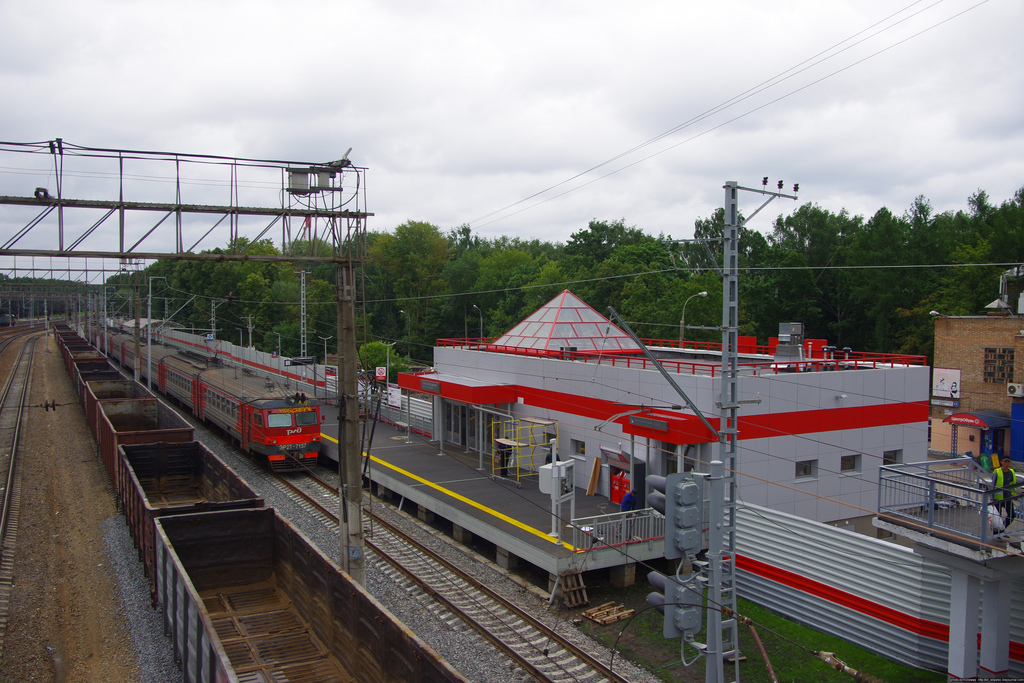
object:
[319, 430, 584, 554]
yellow line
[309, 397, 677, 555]
platform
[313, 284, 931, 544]
train station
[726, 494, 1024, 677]
metal fence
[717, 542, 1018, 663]
red stripe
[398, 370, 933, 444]
red stripe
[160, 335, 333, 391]
red stripe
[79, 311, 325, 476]
train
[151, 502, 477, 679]
empty traincar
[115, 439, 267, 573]
empty traincar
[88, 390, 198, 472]
empty traincar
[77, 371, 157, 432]
empty traincar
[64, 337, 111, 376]
empty traincar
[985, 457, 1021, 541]
person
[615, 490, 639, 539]
person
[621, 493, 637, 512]
blue jacket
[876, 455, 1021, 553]
railing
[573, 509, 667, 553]
railing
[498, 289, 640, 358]
pyramid roof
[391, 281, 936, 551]
building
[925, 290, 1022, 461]
building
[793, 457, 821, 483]
window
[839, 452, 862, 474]
window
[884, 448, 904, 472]
window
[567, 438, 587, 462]
window